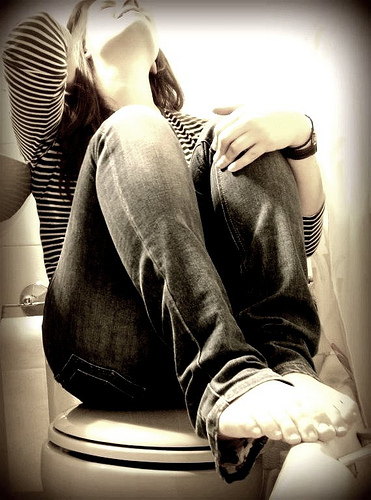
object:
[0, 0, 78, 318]
wall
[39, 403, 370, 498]
toilet